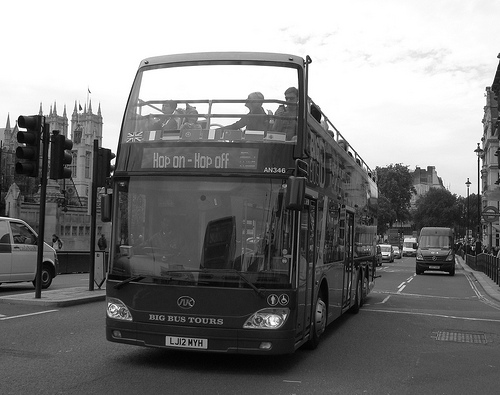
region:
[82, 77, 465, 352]
the bus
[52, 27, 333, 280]
the bus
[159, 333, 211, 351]
white license plate with black letters and numbers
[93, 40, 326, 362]
black and white front of double decker bus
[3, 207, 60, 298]
right side of white van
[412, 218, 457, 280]
front of small dark van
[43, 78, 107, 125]
spires on top of light stone building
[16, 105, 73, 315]
two dark metal traffic lights on pole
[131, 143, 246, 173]
light lettered sign saying hop on hop off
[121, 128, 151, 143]
black and white image of Union Jack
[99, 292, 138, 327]
right headlight of bus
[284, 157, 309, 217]
left hand side mirror of bus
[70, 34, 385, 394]
a bus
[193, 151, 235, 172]
hop off on bus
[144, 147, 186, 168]
hop on on bus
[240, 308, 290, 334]
head light of bus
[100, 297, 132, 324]
head light of bus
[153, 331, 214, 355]
license plate of bus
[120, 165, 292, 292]
front windshield of bus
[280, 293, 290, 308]
handicap sign on bus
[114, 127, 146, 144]
british flag on bus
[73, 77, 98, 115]
flag on top of tower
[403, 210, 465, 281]
van driving on road